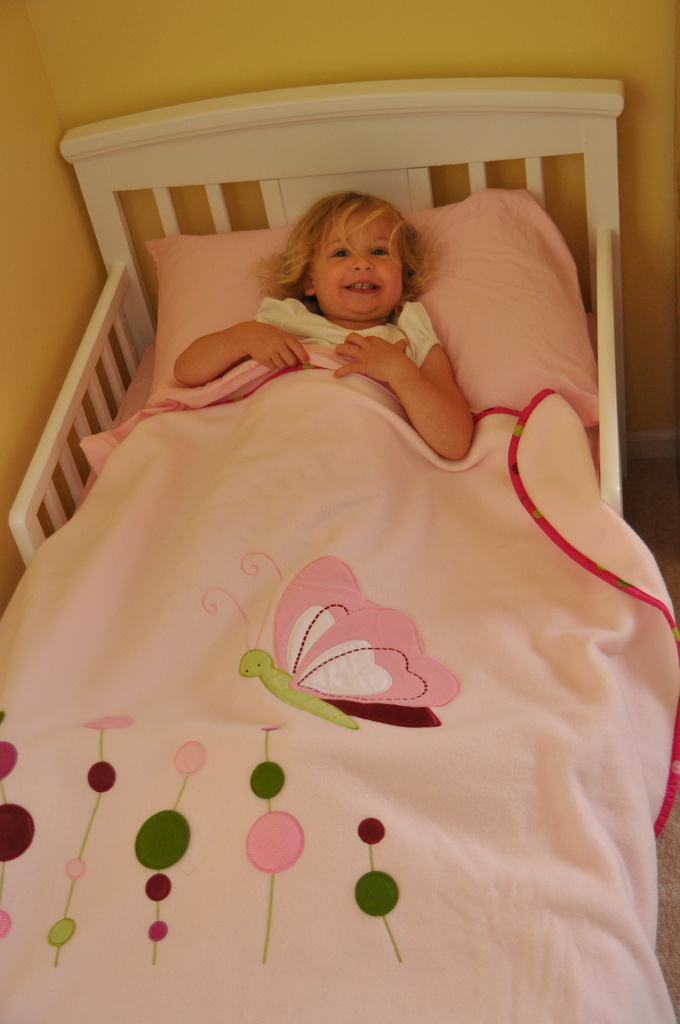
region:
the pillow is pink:
[66, 150, 604, 443]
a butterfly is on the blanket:
[98, 482, 481, 773]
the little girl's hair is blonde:
[252, 182, 431, 319]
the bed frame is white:
[8, 35, 641, 321]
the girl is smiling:
[219, 193, 421, 318]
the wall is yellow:
[296, 1, 673, 177]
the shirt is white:
[212, 284, 460, 395]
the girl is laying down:
[140, 166, 508, 522]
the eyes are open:
[234, 184, 450, 341]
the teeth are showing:
[311, 262, 396, 305]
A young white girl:
[264, 183, 432, 355]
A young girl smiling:
[267, 180, 442, 338]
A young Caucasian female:
[273, 176, 431, 339]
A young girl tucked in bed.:
[142, 194, 591, 468]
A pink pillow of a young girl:
[144, 192, 607, 423]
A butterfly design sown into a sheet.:
[177, 539, 493, 768]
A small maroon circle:
[331, 802, 401, 862]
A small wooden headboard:
[46, 69, 653, 219]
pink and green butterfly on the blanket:
[3, 366, 677, 1022]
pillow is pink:
[140, 190, 598, 425]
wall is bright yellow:
[19, 2, 678, 438]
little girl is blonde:
[168, 190, 477, 465]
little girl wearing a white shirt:
[175, 184, 478, 463]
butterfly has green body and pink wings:
[198, 548, 462, 740]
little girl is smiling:
[175, 190, 477, 463]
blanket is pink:
[8, 360, 678, 1022]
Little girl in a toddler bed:
[94, 133, 522, 760]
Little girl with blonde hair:
[254, 183, 444, 323]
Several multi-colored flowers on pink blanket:
[3, 709, 445, 994]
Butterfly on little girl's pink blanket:
[181, 538, 477, 785]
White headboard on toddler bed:
[34, 45, 633, 385]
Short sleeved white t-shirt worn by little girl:
[242, 281, 442, 415]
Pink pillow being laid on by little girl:
[86, 178, 602, 437]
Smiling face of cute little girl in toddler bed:
[298, 202, 412, 324]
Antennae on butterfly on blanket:
[199, 543, 283, 661]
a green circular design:
[348, 863, 405, 922]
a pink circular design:
[237, 803, 312, 883]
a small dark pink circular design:
[142, 913, 174, 948]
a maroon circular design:
[137, 868, 176, 904]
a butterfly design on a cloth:
[190, 541, 499, 746]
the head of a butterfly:
[235, 642, 275, 683]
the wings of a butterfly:
[277, 553, 483, 705]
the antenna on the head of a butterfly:
[197, 546, 287, 658]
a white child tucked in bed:
[165, 157, 484, 474]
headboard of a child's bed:
[36, 32, 653, 269]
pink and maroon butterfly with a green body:
[193, 544, 463, 736]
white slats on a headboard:
[57, 74, 623, 354]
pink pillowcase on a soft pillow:
[143, 185, 604, 434]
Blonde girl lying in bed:
[152, 177, 476, 465]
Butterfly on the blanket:
[197, 537, 466, 742]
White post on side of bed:
[10, 255, 157, 568]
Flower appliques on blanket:
[0, 702, 411, 974]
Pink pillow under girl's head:
[136, 183, 599, 425]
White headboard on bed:
[58, 67, 628, 286]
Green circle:
[343, 867, 415, 922]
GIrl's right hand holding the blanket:
[249, 323, 316, 380]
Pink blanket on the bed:
[9, 413, 675, 1017]